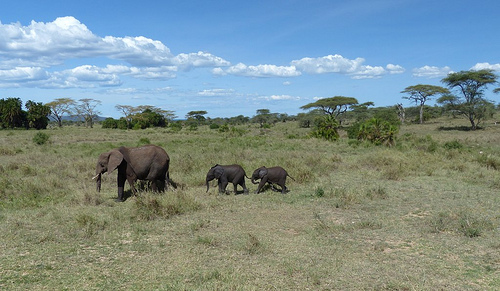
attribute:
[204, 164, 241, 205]
elephant — following, young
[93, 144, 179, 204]
elephant — large, adult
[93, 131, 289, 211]
elephants — walking, grey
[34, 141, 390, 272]
field — green, open, grassy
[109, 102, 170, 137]
tree — green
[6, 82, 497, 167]
trees — green, tall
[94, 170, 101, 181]
tusk — white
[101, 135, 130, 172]
ear — large, wide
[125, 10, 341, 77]
sky — blue, clear, cloudy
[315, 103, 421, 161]
bushes — green, short, small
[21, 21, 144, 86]
clouds — white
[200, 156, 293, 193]
elephants — small, young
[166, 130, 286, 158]
grass — dry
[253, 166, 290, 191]
elephant — young